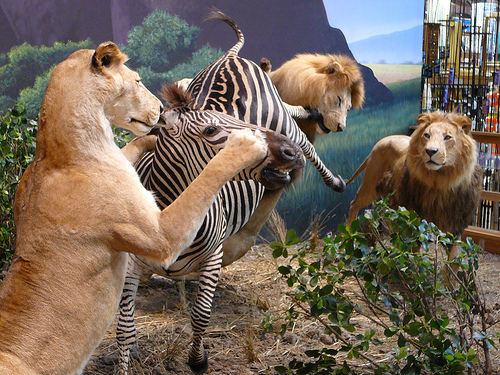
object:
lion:
[340, 105, 487, 298]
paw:
[225, 127, 269, 167]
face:
[179, 109, 306, 191]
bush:
[257, 200, 500, 375]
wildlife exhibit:
[0, 0, 496, 374]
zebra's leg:
[288, 112, 341, 188]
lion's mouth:
[314, 112, 335, 134]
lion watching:
[343, 107, 487, 284]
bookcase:
[417, 0, 500, 248]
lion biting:
[126, 90, 180, 143]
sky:
[322, 0, 497, 62]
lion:
[209, 49, 374, 264]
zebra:
[110, 5, 350, 375]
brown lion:
[2, 41, 270, 373]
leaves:
[272, 248, 282, 260]